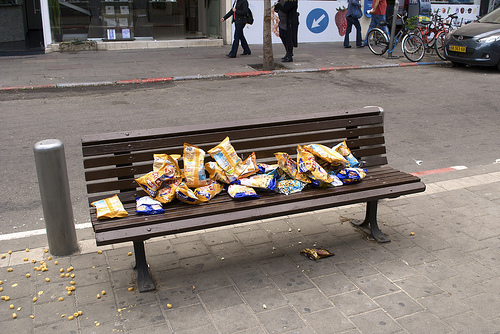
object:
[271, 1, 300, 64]
people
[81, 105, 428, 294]
bench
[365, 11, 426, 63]
bicycles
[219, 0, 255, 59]
pedestrian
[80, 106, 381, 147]
bench edge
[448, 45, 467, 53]
tag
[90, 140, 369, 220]
chips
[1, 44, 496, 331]
street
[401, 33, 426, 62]
tire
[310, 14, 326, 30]
arrow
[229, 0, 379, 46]
wall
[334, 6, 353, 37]
strawberry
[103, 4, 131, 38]
papers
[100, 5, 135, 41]
stand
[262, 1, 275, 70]
tree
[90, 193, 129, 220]
bag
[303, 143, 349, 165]
bag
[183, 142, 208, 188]
bag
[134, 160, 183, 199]
bags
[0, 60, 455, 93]
curb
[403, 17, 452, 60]
bicycles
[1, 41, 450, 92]
sidewalk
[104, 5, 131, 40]
labels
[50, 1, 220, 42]
window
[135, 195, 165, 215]
bag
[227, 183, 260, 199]
bag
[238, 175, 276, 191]
bag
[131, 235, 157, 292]
bottom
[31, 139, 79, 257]
pole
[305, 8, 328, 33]
sign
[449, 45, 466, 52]
license plate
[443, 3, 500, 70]
car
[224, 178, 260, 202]
packets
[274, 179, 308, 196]
packet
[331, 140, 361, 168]
packet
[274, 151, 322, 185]
packet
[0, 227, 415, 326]
cheese pops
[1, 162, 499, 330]
sidewalk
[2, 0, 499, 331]
town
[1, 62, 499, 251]
road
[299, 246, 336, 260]
pack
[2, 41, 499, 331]
ground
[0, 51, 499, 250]
roadside